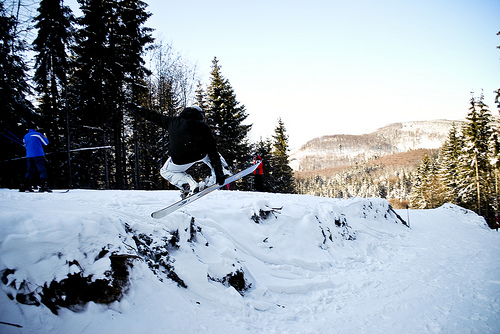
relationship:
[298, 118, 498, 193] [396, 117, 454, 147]
mountain covered in snow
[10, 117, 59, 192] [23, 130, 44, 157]
person wearing jacket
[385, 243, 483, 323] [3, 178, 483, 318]
snow covering ground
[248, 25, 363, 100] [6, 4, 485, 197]
clouds in sky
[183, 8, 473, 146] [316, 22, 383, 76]
cloud in sky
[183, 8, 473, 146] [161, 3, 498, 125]
cloud in sky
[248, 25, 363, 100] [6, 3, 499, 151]
clouds in sky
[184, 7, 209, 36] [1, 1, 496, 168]
clouds in sky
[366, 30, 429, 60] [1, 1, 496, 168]
white clouds in sky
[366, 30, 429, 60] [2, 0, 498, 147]
white clouds in blue sky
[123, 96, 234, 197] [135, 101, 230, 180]
man in sweater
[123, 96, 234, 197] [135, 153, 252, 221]
man on snowboard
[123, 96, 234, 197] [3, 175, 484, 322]
man jumping slope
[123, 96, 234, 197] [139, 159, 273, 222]
man on snowboard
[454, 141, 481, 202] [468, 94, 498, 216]
snow on trees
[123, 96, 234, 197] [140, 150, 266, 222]
man on snowboard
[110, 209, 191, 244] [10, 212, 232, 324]
snow on rock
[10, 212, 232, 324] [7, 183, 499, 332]
rock on slope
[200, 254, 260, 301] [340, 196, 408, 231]
snow on rock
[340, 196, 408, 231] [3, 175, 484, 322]
rock on slope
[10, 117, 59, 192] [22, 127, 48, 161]
person in jacket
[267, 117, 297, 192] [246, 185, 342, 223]
evergreen in hill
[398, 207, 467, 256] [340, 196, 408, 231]
snow covered rock